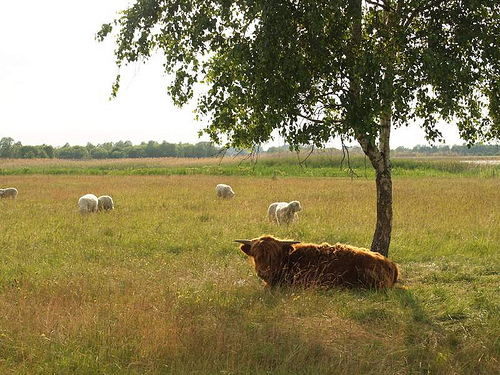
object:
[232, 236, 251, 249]
horn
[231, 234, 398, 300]
bull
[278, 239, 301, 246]
horn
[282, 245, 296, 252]
ear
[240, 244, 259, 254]
ear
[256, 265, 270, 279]
nose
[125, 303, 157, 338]
grass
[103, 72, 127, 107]
leaves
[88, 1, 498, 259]
tree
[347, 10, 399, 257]
trunk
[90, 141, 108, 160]
trees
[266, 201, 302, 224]
sheep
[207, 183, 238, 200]
sheep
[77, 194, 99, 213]
sheep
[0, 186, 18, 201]
sheep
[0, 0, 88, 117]
sky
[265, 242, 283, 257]
fur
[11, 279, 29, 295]
flowers